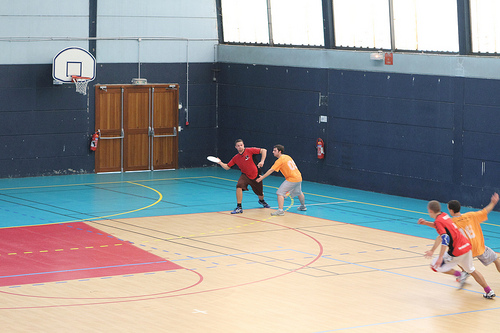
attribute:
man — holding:
[204, 137, 268, 211]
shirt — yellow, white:
[446, 212, 488, 260]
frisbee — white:
[203, 152, 224, 166]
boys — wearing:
[199, 122, 494, 288]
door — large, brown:
[72, 68, 199, 199]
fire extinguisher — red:
[85, 125, 107, 157]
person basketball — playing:
[425, 190, 497, 314]